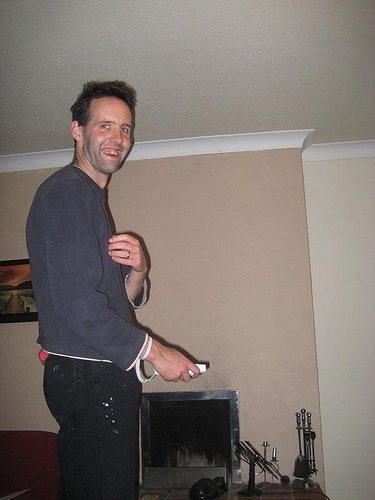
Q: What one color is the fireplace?
A: Black.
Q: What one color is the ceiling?
A: White.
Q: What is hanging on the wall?
A: A picture.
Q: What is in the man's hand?
A: A wii remote.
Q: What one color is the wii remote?
A: White.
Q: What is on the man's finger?
A: A ring.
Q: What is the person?
A: A man.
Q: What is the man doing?
A: Playing games.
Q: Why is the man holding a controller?
A: To play games.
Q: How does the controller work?
A: Motion detection.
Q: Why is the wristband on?
A: To keep the controller in his hand.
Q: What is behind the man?
A: A wall.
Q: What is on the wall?
A: A picture.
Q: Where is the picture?
A: On the wall.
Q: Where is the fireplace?
A: On the wall.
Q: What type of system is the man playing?
A: Wii.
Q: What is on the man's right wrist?
A: Strap.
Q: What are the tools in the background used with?
A: Fireplace.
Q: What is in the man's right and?
A: Wii controller.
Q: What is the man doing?
A: Playing video games.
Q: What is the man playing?
A: Wii.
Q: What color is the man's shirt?
A: Blue.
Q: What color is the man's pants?
A: Black.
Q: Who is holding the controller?
A: A man.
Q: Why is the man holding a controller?
A: To play the game.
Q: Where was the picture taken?
A: Inside a house.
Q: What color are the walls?
A: Beige.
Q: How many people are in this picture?
A: One.